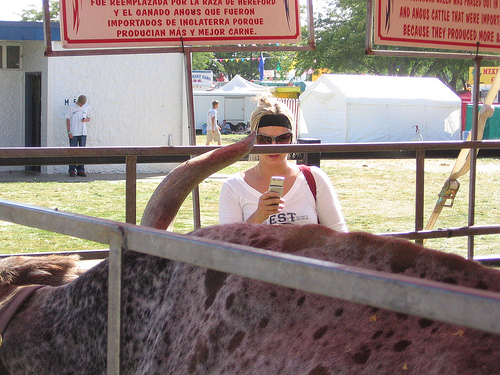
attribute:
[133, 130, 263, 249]
horn — big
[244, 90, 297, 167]
hair — blonde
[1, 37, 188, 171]
wall — white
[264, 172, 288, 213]
phone — silver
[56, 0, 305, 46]
sign — red, white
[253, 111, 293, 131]
headband — black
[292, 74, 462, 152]
tent — white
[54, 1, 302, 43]
sign — white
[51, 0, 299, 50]
sign — white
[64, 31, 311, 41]
border — red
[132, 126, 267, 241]
horn — smooth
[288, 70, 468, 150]
tarp — white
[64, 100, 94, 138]
shirt — white